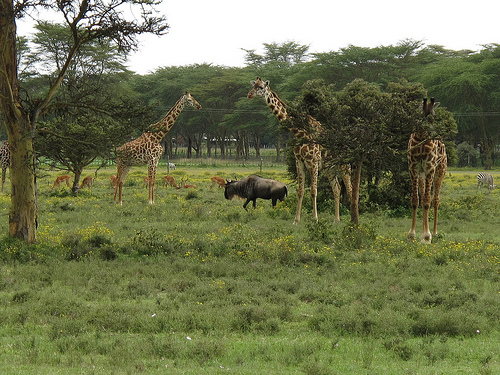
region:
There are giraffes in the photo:
[15, 29, 486, 287]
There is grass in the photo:
[38, 225, 435, 366]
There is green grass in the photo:
[50, 179, 472, 364]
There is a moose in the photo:
[206, 154, 308, 251]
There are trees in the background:
[15, 18, 488, 258]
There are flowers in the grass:
[68, 201, 463, 294]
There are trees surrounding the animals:
[41, 21, 476, 214]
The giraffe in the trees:
[248, 54, 498, 245]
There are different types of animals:
[48, 38, 485, 261]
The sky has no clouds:
[54, 1, 451, 138]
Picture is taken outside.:
[30, 10, 439, 372]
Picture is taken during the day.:
[45, 6, 473, 105]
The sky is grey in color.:
[101, 8, 470, 107]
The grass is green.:
[53, 210, 445, 373]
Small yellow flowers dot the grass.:
[67, 197, 396, 296]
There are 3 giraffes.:
[116, 44, 492, 257]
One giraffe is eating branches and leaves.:
[401, 97, 490, 324]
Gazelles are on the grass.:
[141, 151, 291, 222]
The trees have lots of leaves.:
[146, 47, 453, 205]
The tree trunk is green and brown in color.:
[5, 31, 77, 290]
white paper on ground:
[160, 322, 222, 352]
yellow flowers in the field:
[43, 217, 173, 252]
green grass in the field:
[96, 249, 306, 346]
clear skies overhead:
[228, 10, 380, 28]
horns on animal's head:
[213, 168, 240, 189]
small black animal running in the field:
[210, 165, 324, 223]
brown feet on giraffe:
[97, 175, 200, 210]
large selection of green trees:
[136, 42, 468, 159]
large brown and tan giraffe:
[103, 88, 221, 217]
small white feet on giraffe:
[401, 223, 443, 250]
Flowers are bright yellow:
[37, 213, 487, 280]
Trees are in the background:
[50, 35, 495, 150]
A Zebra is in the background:
[465, 166, 497, 197]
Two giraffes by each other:
[235, 60, 461, 245]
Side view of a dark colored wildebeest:
[200, 165, 285, 220]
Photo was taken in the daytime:
[0, 0, 495, 235]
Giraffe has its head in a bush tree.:
[370, 85, 470, 170]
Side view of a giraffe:
[91, 65, 206, 225]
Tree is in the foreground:
[1, 0, 146, 275]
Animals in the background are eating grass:
[44, 164, 109, 203]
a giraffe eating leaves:
[404, 100, 445, 241]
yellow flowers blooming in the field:
[194, 223, 246, 242]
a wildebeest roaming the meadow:
[223, 166, 290, 216]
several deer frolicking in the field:
[166, 170, 224, 190]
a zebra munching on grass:
[475, 157, 497, 205]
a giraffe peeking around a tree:
[246, 69, 351, 223]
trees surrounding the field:
[209, 49, 457, 88]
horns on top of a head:
[425, 95, 432, 111]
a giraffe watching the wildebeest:
[111, 86, 210, 216]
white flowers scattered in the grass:
[148, 314, 201, 346]